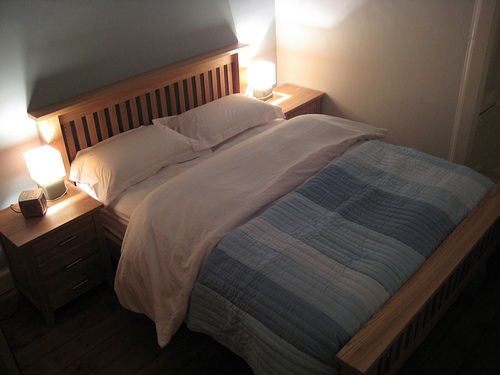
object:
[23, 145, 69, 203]
lamp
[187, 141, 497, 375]
blanket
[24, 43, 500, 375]
bed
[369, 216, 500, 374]
footboard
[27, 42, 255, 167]
headboard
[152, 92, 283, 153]
pillows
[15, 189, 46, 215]
clock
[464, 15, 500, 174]
door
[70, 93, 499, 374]
comforter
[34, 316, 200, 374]
floor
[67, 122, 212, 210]
pillow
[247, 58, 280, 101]
lamp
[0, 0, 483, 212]
wall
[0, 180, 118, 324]
endtable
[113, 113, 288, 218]
sheet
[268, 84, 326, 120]
desk